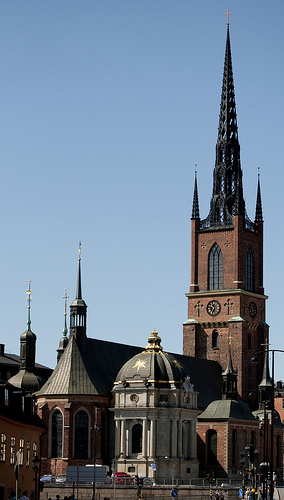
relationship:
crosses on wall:
[193, 295, 241, 320] [186, 290, 241, 318]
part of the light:
[238, 462, 244, 479] [238, 443, 261, 483]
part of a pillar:
[149, 431, 153, 443] [148, 418, 155, 457]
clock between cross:
[205, 300, 222, 317] [192, 300, 203, 317]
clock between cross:
[205, 300, 222, 317] [222, 296, 234, 314]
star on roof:
[126, 356, 150, 372] [113, 339, 186, 387]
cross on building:
[220, 8, 232, 27] [186, 166, 264, 376]